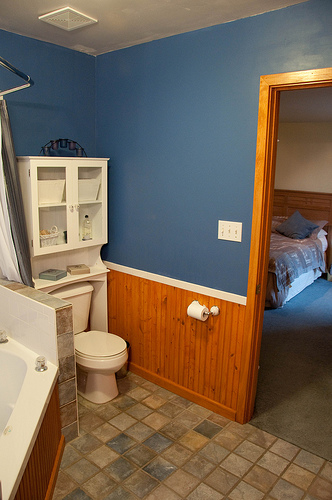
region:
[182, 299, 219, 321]
toilet paper hanging on the wall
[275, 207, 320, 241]
blue pillow on the bed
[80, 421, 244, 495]
tile floor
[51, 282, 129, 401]
white toilet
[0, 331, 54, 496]
corner of the bathtub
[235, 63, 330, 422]
doorway opening into bedroom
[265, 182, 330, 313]
bed with a bedspread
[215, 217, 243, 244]
white light switch on the wall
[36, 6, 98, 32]
white ceiling vent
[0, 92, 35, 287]
grey and white shower curtain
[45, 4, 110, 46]
a beautiful design on wall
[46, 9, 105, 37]
a design attached to wall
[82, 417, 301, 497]
a small pieces of stone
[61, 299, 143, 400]
a beautiful white pingani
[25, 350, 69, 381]
a small screw on table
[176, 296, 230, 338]
a white tissue paper on wall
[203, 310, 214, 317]
a small hanger attached to wall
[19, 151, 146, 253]
a big cup board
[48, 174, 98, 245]
four windows of cup board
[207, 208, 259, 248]
an electric box on wall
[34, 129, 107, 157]
candle holder on top of shelf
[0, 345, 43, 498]
white bath tub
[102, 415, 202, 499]
mixed matched tiles on the floor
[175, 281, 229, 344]
roll of toilet paper in bathroom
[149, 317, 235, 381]
light wood boarding on the wall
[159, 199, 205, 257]
blue paint on the walls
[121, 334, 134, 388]
metal trash bin on the floor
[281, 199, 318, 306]
made up bed in other room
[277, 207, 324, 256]
blue pillow on bed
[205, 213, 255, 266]
light switch with three switches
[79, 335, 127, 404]
this is a toilet sink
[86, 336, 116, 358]
the lid is closed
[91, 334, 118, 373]
the screen is white in color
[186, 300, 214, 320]
this is a tissue roll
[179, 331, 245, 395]
the board is wooden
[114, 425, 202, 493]
the floor is tiled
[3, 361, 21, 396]
this is a sink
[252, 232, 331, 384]
the door is open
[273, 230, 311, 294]
this is a bed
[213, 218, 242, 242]
the switch is white in color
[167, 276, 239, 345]
roll of toilet paper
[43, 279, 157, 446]
white porcelain toilet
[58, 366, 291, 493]
multicolored tile pieces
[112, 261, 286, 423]
orange-brown wooden panel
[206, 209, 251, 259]
set of three light switches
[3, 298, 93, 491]
large white jacuzzi tub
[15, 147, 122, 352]
white shelf over the toilet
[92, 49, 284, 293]
dark blue bathroom wall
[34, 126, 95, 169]
decorate candles sitting on top of shelf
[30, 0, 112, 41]
white vent fan on ceiling